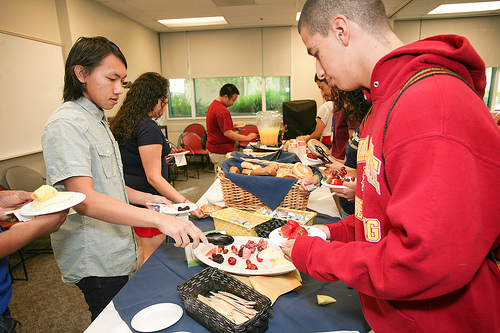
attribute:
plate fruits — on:
[195, 230, 299, 275]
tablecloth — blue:
[110, 209, 365, 331]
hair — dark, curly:
[118, 72, 165, 134]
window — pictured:
[261, 70, 291, 111]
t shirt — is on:
[289, 31, 497, 331]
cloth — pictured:
[235, 276, 303, 306]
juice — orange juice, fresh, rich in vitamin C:
[255, 123, 282, 146]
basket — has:
[203, 154, 318, 216]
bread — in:
[224, 155, 314, 180]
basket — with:
[216, 152, 308, 217]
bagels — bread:
[227, 155, 325, 182]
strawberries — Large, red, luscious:
[276, 218, 318, 246]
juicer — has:
[249, 106, 286, 153]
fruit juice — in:
[256, 128, 277, 146]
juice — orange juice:
[256, 121, 278, 147]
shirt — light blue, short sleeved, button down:
[38, 116, 143, 274]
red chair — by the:
[182, 130, 212, 175]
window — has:
[168, 75, 193, 117]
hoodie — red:
[291, 34, 498, 331]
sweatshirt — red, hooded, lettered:
[311, 55, 482, 328]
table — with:
[138, 271, 183, 330]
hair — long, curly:
[121, 73, 169, 138]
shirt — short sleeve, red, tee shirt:
[201, 98, 241, 150]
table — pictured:
[266, 285, 316, 330]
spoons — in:
[196, 288, 251, 327]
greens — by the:
[175, 91, 283, 112]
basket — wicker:
[218, 154, 309, 211]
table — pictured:
[82, 143, 370, 331]